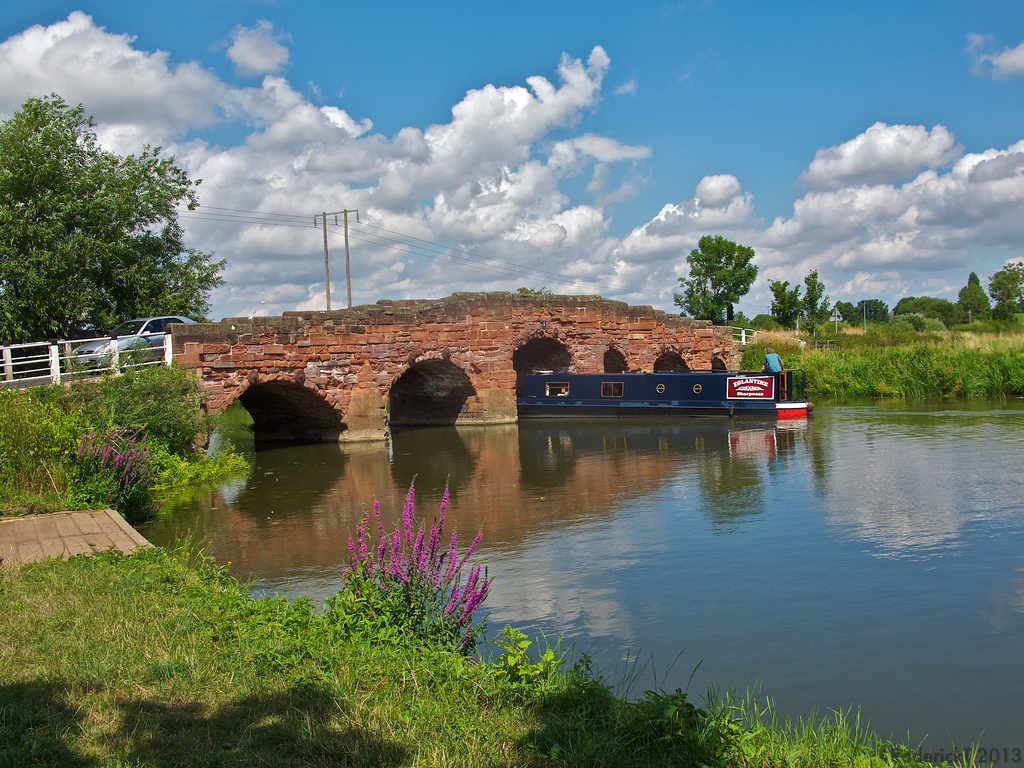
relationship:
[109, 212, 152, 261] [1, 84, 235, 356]
green leaves on tree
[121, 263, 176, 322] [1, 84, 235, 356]
green leaves on tree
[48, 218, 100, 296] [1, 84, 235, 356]
green leaves on tree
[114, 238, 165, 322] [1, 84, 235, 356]
green leaves on tree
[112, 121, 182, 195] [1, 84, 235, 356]
green leaves on tree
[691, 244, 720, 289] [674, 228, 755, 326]
green leaves on tree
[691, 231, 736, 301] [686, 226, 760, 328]
green leaves on tree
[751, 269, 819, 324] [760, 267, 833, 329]
green leaves on tree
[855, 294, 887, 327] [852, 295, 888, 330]
green leaves on tree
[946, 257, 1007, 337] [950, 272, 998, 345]
green leaves on tree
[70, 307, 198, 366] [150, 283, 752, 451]
car on bridge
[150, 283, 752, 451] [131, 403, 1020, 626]
bridge over water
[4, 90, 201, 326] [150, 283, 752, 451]
green tree near bridge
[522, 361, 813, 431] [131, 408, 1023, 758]
boat in river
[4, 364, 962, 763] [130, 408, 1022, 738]
grass near river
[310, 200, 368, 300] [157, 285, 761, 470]
telephone poles behind bridge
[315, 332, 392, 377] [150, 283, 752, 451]
rocks near bridge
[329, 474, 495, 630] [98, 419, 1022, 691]
purple plants near river